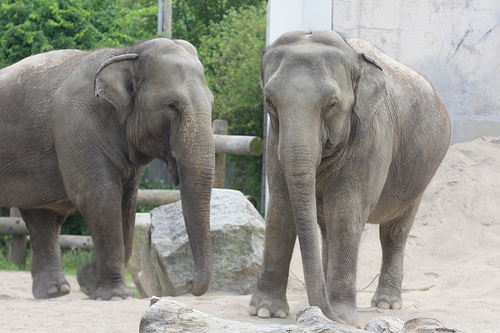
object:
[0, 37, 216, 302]
elephant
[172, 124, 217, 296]
trunk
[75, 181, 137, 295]
front legs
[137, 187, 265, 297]
rock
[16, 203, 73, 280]
back leg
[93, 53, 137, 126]
ear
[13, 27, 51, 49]
leaves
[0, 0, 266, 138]
trees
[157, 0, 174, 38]
post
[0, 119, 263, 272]
fence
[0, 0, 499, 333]
zoo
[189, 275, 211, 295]
end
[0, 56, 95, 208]
skin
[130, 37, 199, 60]
lumps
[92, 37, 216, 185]
head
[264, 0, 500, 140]
wall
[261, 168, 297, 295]
leg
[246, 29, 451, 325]
elephant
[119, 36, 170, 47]
hair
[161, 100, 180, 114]
eyes